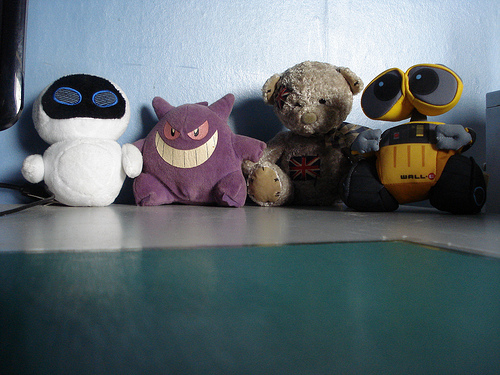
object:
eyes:
[163, 117, 210, 141]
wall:
[2, 1, 222, 88]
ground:
[361, 151, 392, 176]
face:
[43, 73, 126, 123]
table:
[0, 200, 500, 373]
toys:
[19, 61, 479, 225]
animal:
[16, 61, 149, 218]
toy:
[130, 91, 269, 208]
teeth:
[145, 130, 217, 168]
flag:
[394, 167, 440, 186]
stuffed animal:
[341, 61, 486, 216]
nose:
[300, 106, 321, 130]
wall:
[259, 3, 496, 89]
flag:
[282, 153, 324, 182]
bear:
[244, 59, 386, 208]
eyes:
[279, 97, 329, 107]